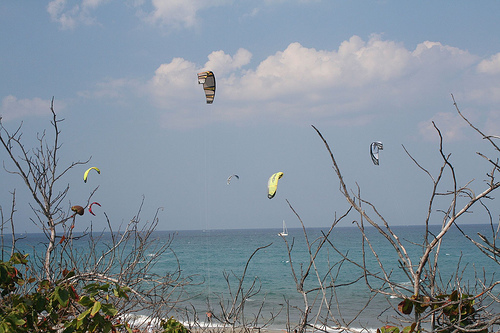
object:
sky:
[1, 0, 498, 67]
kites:
[192, 66, 221, 106]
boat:
[275, 216, 290, 240]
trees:
[0, 99, 167, 333]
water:
[178, 229, 238, 255]